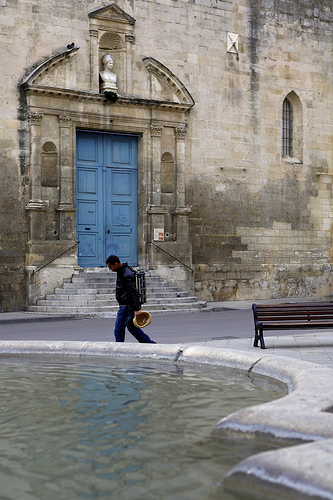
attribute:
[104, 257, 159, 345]
man — walking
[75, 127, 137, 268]
door — blue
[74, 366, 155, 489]
reflection — of the blue door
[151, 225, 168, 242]
signage — painted with red color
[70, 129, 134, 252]
doors — blue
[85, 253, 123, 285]
hair — dark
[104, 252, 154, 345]
man — walking around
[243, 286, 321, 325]
bench — empty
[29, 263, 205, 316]
steps — concrete